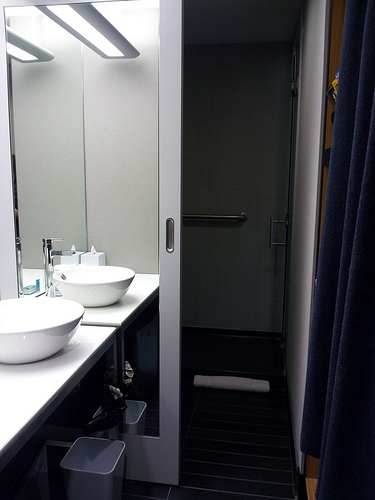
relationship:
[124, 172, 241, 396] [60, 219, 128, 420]
mirror for bathroom